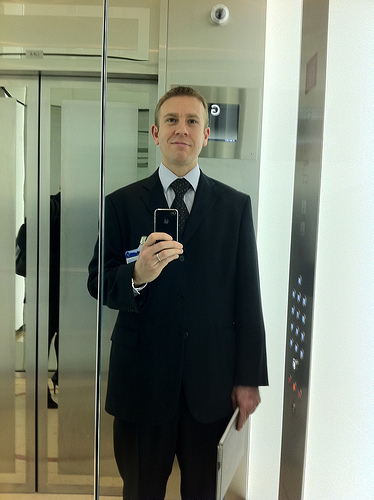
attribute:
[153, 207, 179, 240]
phone — black, silver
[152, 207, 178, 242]
phone — black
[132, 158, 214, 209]
shirt — white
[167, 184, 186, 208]
tie — black